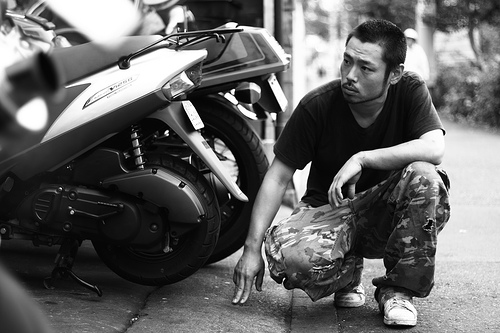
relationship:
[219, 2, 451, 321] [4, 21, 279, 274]
man next to motorcycle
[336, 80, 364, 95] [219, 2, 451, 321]
mustache of man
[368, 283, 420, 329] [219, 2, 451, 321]
sneaker of man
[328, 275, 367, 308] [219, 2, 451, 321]
sneaker of man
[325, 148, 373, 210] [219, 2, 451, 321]
hand of man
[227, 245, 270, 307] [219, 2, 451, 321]
hand of man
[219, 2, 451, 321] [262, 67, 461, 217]
man wearing t shirt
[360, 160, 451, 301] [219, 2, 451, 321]
leg of man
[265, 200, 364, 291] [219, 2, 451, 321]
leg of man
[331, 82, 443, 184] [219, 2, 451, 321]
arm of man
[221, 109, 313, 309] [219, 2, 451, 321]
arm of man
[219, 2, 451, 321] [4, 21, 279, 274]
man by motorcycle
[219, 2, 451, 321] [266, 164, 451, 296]
man wearing pants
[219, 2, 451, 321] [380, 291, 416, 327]
man wearing sneaker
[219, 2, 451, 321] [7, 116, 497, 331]
man touching ground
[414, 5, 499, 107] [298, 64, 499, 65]
trees in background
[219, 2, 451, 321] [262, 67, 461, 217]
man in t shirt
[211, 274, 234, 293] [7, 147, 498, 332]
pebbles on ground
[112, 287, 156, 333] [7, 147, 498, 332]
groove on ground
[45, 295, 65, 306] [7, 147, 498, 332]
oil slick on ground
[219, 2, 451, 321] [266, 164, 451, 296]
man has pants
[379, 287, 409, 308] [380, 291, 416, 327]
laces in sneaker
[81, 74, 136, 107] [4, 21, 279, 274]
logo on bike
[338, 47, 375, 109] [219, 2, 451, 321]
face of man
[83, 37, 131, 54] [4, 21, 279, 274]
shine on bike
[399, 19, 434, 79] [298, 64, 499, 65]
man in background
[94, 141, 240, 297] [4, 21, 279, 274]
tire of motorcycle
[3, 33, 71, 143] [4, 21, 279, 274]
exhaust pipe of motorcycle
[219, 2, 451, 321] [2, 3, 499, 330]
man in photo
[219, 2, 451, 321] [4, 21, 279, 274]
man behind motorcycle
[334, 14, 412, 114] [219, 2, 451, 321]
head of man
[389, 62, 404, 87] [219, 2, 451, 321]
ear of man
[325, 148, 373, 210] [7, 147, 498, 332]
hand touching ground